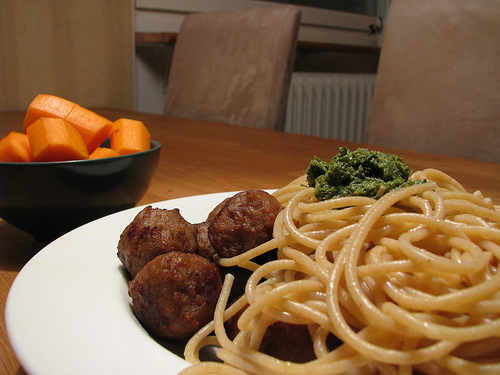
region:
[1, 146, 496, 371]
food is on a white round plate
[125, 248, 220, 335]
brown round meatballs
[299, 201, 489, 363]
several spaghetti noodles on a plate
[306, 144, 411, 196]
pile of pesto on spghetti noodles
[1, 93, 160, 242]
cut carrots in a black bowl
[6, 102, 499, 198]
table is made of wood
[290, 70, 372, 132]
white radiator is against the wall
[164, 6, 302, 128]
plush tan dining room chair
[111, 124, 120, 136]
dark spot on carrot slice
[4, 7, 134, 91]
tan wall has darker stripes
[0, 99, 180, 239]
carrots in a bowl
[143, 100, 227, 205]
the table is brown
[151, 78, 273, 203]
the table is brown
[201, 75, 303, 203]
the table is brown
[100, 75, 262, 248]
the table is brown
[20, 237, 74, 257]
Edge of white plate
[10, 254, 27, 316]
Edge of white plate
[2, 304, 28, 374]
Edge of white plate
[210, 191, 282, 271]
Brown ball of meat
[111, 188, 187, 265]
Brown ball of meat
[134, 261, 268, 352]
Brown ball of meat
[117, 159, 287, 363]
Brown balls of meat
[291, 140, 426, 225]
Green thick paste on noodles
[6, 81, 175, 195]
Orange food on black bowl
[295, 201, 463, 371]
White noodles in a bowl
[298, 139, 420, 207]
a green paste on pasta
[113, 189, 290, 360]
the meatballs are brown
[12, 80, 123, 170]
the carrots are sliced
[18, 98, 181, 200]
the carrots are sliced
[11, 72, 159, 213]
This is a fruit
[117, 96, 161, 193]
This is a fruit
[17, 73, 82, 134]
This is a fruit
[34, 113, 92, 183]
This is a fruit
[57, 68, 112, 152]
This is a fruit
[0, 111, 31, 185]
This is a fruit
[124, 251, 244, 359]
This is a meat ball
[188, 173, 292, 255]
This is a meat ball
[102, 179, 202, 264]
This is a meat ball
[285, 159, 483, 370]
These are nudules